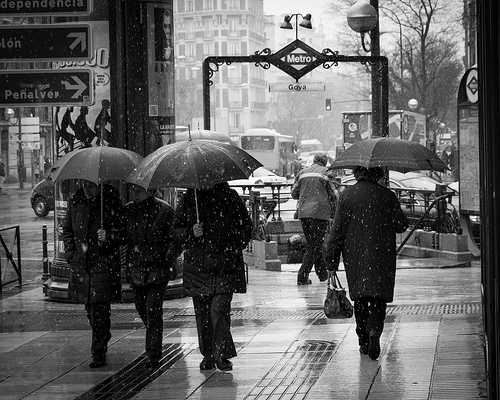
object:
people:
[42, 151, 447, 371]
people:
[173, 151, 408, 371]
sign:
[253, 41, 324, 87]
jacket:
[290, 164, 341, 224]